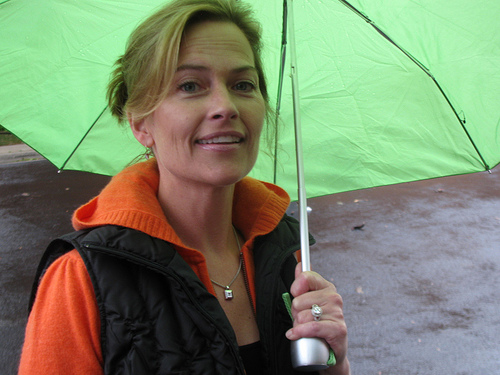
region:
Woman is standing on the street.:
[4, 4, 498, 374]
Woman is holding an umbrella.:
[6, 3, 493, 373]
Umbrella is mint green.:
[3, 4, 498, 211]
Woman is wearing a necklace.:
[126, 165, 276, 315]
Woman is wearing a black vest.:
[31, 197, 347, 372]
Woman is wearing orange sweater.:
[9, 158, 359, 373]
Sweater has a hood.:
[16, 155, 355, 373]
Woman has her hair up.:
[78, 3, 316, 198]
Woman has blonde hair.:
[73, 0, 320, 202]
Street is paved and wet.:
[0, 159, 499, 373]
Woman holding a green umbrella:
[0, 0, 496, 370]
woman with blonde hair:
[25, 1, 350, 373]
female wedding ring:
[311, 303, 321, 321]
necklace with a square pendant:
[176, 218, 243, 300]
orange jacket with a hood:
[15, 158, 292, 373]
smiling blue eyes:
[172, 78, 254, 96]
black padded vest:
[25, 208, 316, 373]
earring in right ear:
[142, 139, 149, 158]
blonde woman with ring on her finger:
[20, 1, 347, 373]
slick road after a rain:
[0, 154, 496, 374]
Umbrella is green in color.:
[311, 60, 391, 145]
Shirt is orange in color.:
[51, 305, 82, 368]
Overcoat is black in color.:
[121, 284, 206, 356]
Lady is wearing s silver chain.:
[211, 248, 284, 356]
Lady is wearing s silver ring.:
[308, 299, 323, 326]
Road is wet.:
[372, 227, 468, 322]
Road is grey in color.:
[361, 236, 460, 326]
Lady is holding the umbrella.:
[281, 252, 372, 364]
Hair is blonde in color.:
[136, 33, 168, 64]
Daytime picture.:
[45, 58, 424, 368]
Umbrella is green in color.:
[316, 37, 479, 183]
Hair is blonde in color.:
[129, 36, 165, 85]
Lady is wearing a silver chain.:
[201, 251, 287, 312]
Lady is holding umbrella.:
[271, 258, 358, 374]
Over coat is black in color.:
[131, 278, 201, 365]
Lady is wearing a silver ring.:
[312, 303, 325, 325]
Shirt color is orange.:
[29, 294, 77, 374]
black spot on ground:
[345, 220, 376, 237]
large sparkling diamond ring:
[301, 300, 325, 324]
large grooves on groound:
[390, 262, 461, 329]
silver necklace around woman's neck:
[210, 276, 245, 298]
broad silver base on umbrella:
[282, 329, 337, 364]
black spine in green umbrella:
[27, 137, 105, 179]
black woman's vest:
[64, 227, 210, 312]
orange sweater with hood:
[83, 184, 168, 228]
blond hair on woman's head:
[94, 6, 314, 71]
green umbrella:
[30, 4, 118, 109]